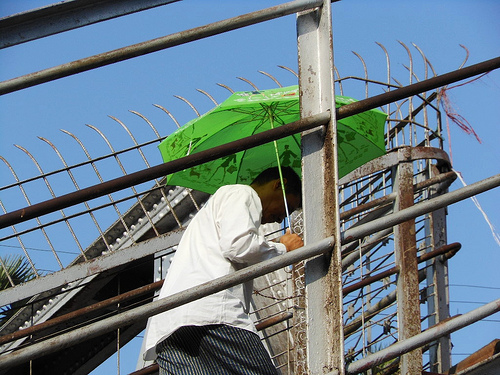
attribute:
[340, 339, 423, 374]
tree — palm, one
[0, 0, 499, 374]
metal railing — rusted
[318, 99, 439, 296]
poles — metal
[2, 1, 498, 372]
railing — metallic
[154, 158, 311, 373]
man — one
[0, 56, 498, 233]
pole — rusty, metal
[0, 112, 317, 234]
rusty bar — one, vertical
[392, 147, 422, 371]
metal post — one, metallic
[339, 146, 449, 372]
poles — metallic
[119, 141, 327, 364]
man — one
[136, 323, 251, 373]
bottoms — black, gray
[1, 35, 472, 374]
fence — large, metal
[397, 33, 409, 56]
spike — metal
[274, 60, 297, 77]
spike — metal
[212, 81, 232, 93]
spike — metal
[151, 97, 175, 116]
spike — metal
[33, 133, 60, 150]
spike — metal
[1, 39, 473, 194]
top — fence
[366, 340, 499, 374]
stairs — some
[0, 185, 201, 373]
stairs — some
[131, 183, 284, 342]
shirt — untucked, one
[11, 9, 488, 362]
sky — blue, clear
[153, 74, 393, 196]
umbrella — one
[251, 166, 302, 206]
black hair — short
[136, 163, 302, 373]
man — one, green, white, ascending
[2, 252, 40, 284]
palm leaves — tree, some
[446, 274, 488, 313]
lines — some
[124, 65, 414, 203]
umbrella — one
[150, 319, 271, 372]
pants — black and white, striped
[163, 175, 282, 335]
shirt — white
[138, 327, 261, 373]
pants — striped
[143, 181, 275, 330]
shirt — one, white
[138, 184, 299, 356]
shirt — one, long-sleeved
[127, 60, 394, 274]
umbrella — one, green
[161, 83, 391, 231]
umbrella — one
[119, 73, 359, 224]
canopy — green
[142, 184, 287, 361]
white coat — one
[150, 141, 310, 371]
man — one